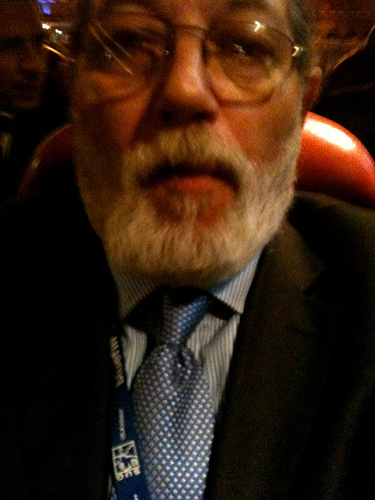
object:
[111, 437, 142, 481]
tag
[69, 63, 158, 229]
cheek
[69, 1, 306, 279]
face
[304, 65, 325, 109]
ear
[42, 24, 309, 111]
spectacles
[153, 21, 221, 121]
nose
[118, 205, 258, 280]
chin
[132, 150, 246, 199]
mouth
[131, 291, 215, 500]
tie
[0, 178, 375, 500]
coat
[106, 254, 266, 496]
shirt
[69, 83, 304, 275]
beard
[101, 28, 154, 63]
eye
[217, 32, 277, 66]
eye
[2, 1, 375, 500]
man